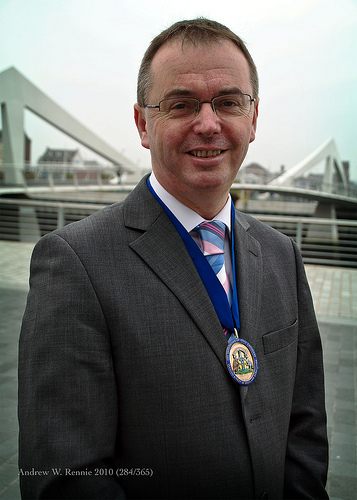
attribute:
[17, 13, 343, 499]
man — smiling, middle-aged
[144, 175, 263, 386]
medal — blue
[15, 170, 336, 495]
suit — nice, gray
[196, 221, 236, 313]
tie — colorful, pink, white, blue, striped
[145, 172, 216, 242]
shirt — white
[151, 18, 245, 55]
hair — short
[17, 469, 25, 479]
letter a — white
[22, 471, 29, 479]
letter n — white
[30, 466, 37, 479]
letter d — white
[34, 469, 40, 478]
letter r — white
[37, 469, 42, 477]
letter e — white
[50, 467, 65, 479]
letter w — white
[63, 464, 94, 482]
word — white, rennie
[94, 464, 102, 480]
number 2 — white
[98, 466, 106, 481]
number 0 — white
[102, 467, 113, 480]
number one — white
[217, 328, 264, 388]
medalion — gold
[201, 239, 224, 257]
stripe — pink, blue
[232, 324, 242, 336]
ring — gold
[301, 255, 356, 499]
pavement — concrete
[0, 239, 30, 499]
pavement — concrete